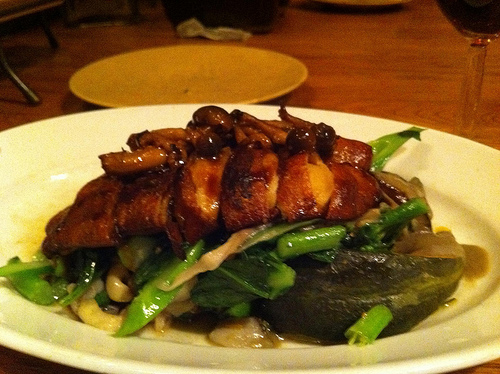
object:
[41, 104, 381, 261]
meat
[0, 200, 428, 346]
vegetables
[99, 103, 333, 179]
mushrooms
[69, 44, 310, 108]
plate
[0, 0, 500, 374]
table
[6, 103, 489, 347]
food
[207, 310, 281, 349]
sauce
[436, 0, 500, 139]
glass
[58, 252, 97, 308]
leaf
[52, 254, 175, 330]
onions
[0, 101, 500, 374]
plate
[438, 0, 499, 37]
wine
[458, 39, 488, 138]
stem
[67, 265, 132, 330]
noodle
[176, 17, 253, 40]
plastic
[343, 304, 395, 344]
bean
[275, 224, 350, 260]
bean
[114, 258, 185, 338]
bean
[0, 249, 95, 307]
bean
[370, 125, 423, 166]
bean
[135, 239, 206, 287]
shallots